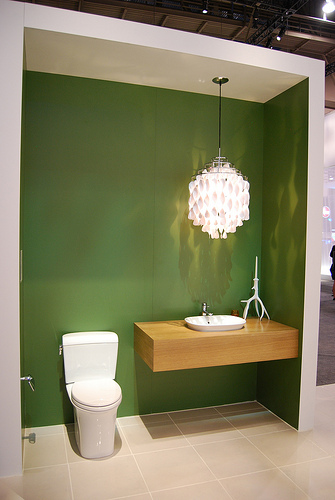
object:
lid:
[53, 323, 126, 346]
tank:
[60, 340, 119, 380]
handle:
[59, 343, 63, 355]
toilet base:
[70, 406, 119, 459]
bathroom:
[23, 68, 308, 497]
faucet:
[199, 299, 216, 321]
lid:
[71, 378, 121, 406]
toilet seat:
[70, 399, 124, 411]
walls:
[19, 69, 308, 428]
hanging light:
[183, 73, 252, 241]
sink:
[179, 315, 248, 332]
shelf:
[133, 312, 301, 372]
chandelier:
[188, 159, 253, 240]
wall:
[99, 154, 175, 245]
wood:
[160, 349, 178, 363]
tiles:
[165, 413, 310, 486]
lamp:
[186, 75, 261, 253]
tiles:
[23, 410, 330, 498]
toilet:
[63, 335, 125, 461]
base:
[74, 406, 117, 458]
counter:
[140, 329, 287, 371]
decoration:
[239, 255, 274, 322]